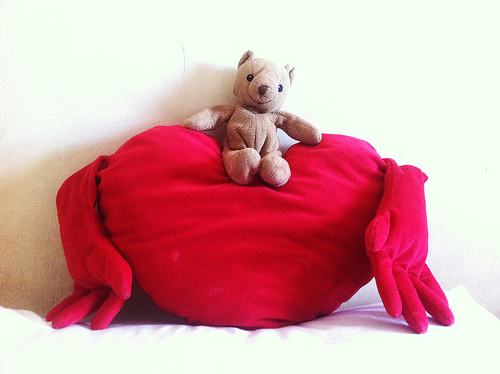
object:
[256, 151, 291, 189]
bearleg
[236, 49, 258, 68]
ear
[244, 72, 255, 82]
eye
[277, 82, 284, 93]
eye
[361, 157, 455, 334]
hands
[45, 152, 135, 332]
hands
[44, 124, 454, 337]
heart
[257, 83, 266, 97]
nose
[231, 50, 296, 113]
head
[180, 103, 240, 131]
arm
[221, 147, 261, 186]
leg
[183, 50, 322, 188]
bear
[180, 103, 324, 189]
body